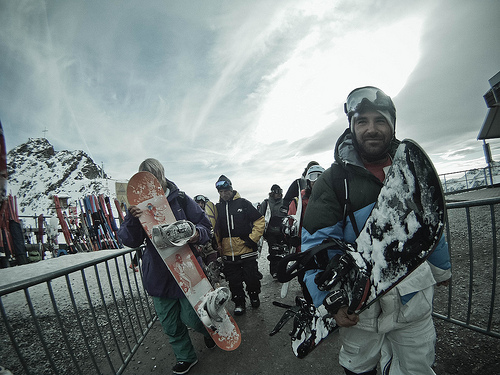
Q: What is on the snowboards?
A: Snow.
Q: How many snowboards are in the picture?
A: Five.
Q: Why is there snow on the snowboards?
A: They were in the snow.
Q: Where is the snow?
A: On the snowboards.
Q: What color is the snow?
A: White.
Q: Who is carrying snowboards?
A: Men.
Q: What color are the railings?
A: Silver.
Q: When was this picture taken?
A: During the day.